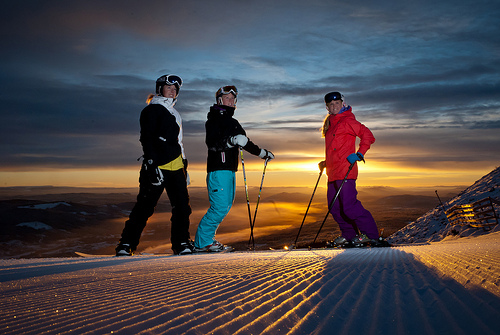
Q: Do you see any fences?
A: No, there are no fences.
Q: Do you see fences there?
A: No, there are no fences.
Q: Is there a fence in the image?
A: No, there are no fences.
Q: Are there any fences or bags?
A: No, there are no fences or bags.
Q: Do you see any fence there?
A: No, there are no fences.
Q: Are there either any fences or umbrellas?
A: No, there are no fences or umbrellas.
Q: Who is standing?
A: The people are standing.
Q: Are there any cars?
A: No, there are no cars.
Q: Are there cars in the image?
A: No, there are no cars.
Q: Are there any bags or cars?
A: No, there are no cars or bags.